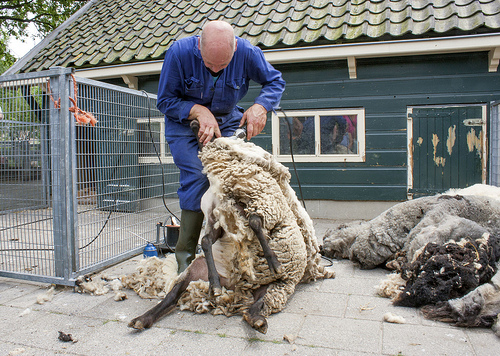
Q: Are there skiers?
A: No, there are no skiers.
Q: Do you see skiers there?
A: No, there are no skiers.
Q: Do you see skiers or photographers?
A: No, there are no skiers or photographers.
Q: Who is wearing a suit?
A: The man is wearing a suit.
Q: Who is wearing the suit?
A: The man is wearing a suit.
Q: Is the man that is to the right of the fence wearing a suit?
A: Yes, the man is wearing a suit.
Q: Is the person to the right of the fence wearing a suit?
A: Yes, the man is wearing a suit.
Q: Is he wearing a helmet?
A: No, the man is wearing a suit.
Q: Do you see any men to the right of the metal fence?
A: Yes, there is a man to the right of the fence.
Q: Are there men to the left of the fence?
A: No, the man is to the right of the fence.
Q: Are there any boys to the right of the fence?
A: No, there is a man to the right of the fence.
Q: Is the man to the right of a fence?
A: Yes, the man is to the right of a fence.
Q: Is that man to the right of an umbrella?
A: No, the man is to the right of a fence.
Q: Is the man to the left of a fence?
A: No, the man is to the right of a fence.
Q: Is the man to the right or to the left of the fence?
A: The man is to the right of the fence.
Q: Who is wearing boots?
A: The man is wearing boots.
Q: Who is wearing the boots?
A: The man is wearing boots.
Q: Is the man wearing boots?
A: Yes, the man is wearing boots.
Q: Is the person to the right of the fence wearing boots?
A: Yes, the man is wearing boots.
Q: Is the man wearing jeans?
A: No, the man is wearing boots.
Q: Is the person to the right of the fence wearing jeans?
A: No, the man is wearing boots.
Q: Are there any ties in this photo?
A: No, there are no ties.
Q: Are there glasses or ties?
A: No, there are no ties or glasses.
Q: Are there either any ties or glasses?
A: No, there are no ties or glasses.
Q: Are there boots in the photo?
A: Yes, there are boots.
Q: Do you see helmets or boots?
A: Yes, there are boots.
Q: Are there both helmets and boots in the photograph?
A: No, there are boots but no helmets.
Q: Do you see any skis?
A: No, there are no skis.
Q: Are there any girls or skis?
A: No, there are no skis or girls.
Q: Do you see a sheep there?
A: Yes, there is a sheep.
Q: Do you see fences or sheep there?
A: Yes, there is a sheep.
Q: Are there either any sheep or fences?
A: Yes, there is a sheep.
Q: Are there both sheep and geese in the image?
A: No, there is a sheep but no geese.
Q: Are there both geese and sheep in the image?
A: No, there is a sheep but no geese.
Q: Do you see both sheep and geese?
A: No, there is a sheep but no geese.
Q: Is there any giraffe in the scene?
A: No, there are no giraffes.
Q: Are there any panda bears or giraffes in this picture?
A: No, there are no giraffes or panda bears.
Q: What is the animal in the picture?
A: The animal is a sheep.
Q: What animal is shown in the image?
A: The animal is a sheep.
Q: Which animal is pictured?
A: The animal is a sheep.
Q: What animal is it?
A: The animal is a sheep.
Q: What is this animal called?
A: That is a sheep.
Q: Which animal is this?
A: That is a sheep.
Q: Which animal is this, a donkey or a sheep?
A: That is a sheep.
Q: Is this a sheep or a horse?
A: This is a sheep.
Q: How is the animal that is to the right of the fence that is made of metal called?
A: The animal is a sheep.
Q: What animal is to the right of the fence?
A: The animal is a sheep.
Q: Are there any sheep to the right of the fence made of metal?
A: Yes, there is a sheep to the right of the fence.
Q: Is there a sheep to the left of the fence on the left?
A: No, the sheep is to the right of the fence.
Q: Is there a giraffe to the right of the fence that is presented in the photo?
A: No, there is a sheep to the right of the fence.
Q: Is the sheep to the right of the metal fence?
A: Yes, the sheep is to the right of the fence.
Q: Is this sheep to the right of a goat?
A: No, the sheep is to the right of the fence.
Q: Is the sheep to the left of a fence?
A: No, the sheep is to the right of a fence.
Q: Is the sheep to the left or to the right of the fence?
A: The sheep is to the right of the fence.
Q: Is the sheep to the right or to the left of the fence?
A: The sheep is to the right of the fence.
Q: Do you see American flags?
A: No, there are no American flags.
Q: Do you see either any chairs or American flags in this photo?
A: No, there are no American flags or chairs.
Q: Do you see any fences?
A: Yes, there is a fence.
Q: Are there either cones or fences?
A: Yes, there is a fence.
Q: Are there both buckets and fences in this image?
A: No, there is a fence but no buckets.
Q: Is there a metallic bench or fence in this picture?
A: Yes, there is a metal fence.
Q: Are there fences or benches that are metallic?
A: Yes, the fence is metallic.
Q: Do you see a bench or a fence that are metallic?
A: Yes, the fence is metallic.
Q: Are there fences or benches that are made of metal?
A: Yes, the fence is made of metal.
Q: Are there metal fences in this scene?
A: Yes, there is a metal fence.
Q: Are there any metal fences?
A: Yes, there is a metal fence.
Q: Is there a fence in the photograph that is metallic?
A: Yes, there is a fence that is metallic.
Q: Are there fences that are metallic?
A: Yes, there is a fence that is metallic.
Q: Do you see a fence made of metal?
A: Yes, there is a fence that is made of metal.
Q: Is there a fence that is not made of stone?
A: Yes, there is a fence that is made of metal.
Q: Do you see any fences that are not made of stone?
A: Yes, there is a fence that is made of metal.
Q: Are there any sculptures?
A: No, there are no sculptures.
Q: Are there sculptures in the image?
A: No, there are no sculptures.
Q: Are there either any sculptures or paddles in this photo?
A: No, there are no sculptures or paddles.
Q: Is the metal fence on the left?
A: Yes, the fence is on the left of the image.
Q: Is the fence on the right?
A: No, the fence is on the left of the image.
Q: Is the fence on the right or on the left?
A: The fence is on the left of the image.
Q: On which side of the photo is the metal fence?
A: The fence is on the left of the image.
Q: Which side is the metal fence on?
A: The fence is on the left of the image.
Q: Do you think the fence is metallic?
A: Yes, the fence is metallic.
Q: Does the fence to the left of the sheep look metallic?
A: Yes, the fence is metallic.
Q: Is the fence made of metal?
A: Yes, the fence is made of metal.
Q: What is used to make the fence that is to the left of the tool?
A: The fence is made of metal.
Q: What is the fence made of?
A: The fence is made of metal.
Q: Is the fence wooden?
A: No, the fence is metallic.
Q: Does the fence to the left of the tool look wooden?
A: No, the fence is metallic.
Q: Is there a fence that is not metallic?
A: No, there is a fence but it is metallic.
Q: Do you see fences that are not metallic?
A: No, there is a fence but it is metallic.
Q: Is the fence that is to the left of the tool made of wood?
A: No, the fence is made of metal.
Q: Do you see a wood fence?
A: No, there is a fence but it is made of metal.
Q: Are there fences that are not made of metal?
A: No, there is a fence but it is made of metal.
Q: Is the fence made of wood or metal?
A: The fence is made of metal.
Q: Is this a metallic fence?
A: Yes, this is a metallic fence.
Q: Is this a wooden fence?
A: No, this is a metallic fence.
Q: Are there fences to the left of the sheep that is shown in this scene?
A: Yes, there is a fence to the left of the sheep.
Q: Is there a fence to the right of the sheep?
A: No, the fence is to the left of the sheep.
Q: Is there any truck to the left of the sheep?
A: No, there is a fence to the left of the sheep.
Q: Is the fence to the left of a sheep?
A: Yes, the fence is to the left of a sheep.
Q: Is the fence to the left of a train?
A: No, the fence is to the left of a sheep.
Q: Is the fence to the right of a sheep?
A: No, the fence is to the left of a sheep.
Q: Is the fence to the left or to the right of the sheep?
A: The fence is to the left of the sheep.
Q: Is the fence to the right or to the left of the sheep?
A: The fence is to the left of the sheep.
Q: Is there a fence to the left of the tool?
A: Yes, there is a fence to the left of the tool.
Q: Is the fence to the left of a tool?
A: Yes, the fence is to the left of a tool.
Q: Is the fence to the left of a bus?
A: No, the fence is to the left of a tool.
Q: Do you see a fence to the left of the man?
A: Yes, there is a fence to the left of the man.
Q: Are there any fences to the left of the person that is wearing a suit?
A: Yes, there is a fence to the left of the man.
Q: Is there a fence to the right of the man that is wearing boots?
A: No, the fence is to the left of the man.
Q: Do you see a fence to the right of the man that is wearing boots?
A: No, the fence is to the left of the man.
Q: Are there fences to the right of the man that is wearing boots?
A: No, the fence is to the left of the man.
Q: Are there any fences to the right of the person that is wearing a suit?
A: No, the fence is to the left of the man.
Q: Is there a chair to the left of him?
A: No, there is a fence to the left of the man.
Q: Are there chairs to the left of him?
A: No, there is a fence to the left of the man.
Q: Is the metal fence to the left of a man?
A: Yes, the fence is to the left of a man.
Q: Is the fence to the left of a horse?
A: No, the fence is to the left of a man.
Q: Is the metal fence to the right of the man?
A: No, the fence is to the left of the man.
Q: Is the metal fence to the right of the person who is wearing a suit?
A: No, the fence is to the left of the man.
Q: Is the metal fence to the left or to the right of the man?
A: The fence is to the left of the man.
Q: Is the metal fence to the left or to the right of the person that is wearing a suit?
A: The fence is to the left of the man.